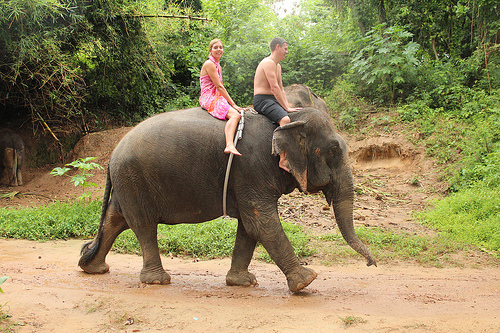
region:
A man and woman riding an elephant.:
[56, 11, 424, 320]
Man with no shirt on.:
[246, 26, 293, 110]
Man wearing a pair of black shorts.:
[242, 33, 314, 131]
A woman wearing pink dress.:
[186, 25, 251, 161]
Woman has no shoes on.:
[191, 41, 253, 168]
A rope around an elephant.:
[219, 98, 246, 227]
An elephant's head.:
[270, 101, 358, 201]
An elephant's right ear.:
[271, 112, 323, 206]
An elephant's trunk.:
[301, 105, 399, 278]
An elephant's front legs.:
[221, 87, 368, 320]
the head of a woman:
[206, 35, 227, 61]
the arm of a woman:
[207, 62, 237, 105]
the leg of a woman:
[212, 102, 243, 145]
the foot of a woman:
[222, 142, 245, 157]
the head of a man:
[267, 35, 292, 60]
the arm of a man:
[263, 59, 291, 111]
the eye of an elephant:
[328, 141, 343, 156]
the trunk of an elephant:
[332, 173, 380, 268]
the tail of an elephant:
[76, 162, 116, 270]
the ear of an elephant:
[268, 120, 318, 199]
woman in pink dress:
[188, 35, 240, 162]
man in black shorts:
[251, 26, 316, 156]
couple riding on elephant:
[82, 24, 350, 296]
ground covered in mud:
[383, 282, 470, 322]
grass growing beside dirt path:
[445, 180, 497, 235]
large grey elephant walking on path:
[54, 103, 370, 331]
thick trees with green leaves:
[0, 0, 171, 105]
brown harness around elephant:
[210, 167, 239, 226]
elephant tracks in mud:
[398, 284, 466, 314]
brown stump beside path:
[0, 139, 27, 189]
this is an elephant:
[61, 72, 408, 308]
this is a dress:
[200, 63, 237, 120]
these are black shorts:
[254, 89, 291, 125]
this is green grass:
[52, 205, 76, 225]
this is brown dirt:
[350, 281, 372, 301]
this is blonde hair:
[197, 32, 223, 59]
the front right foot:
[276, 254, 320, 296]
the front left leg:
[221, 251, 262, 296]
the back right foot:
[133, 250, 183, 297]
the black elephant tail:
[78, 157, 116, 282]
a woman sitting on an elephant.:
[195, 32, 242, 162]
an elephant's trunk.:
[327, 182, 384, 270]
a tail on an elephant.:
[67, 178, 118, 277]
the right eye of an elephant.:
[313, 144, 348, 171]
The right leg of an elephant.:
[233, 219, 325, 293]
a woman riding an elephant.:
[197, 26, 247, 173]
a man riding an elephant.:
[243, 26, 320, 184]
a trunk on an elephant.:
[319, 183, 395, 286]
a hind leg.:
[125, 187, 196, 309]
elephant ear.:
[258, 116, 327, 203]